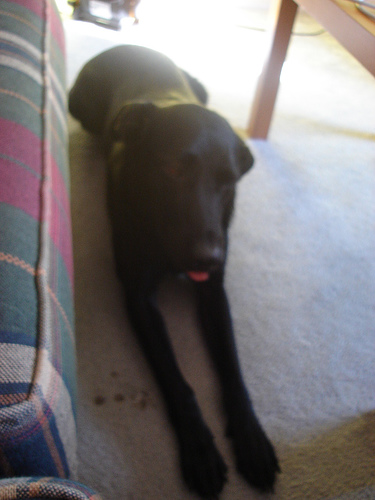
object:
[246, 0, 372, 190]
chair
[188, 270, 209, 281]
tongue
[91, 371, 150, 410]
stain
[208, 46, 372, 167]
carpet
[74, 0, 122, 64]
carpet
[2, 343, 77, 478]
stripe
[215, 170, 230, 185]
eye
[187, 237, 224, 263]
nose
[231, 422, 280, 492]
paw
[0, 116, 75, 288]
pink stripe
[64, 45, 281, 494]
dog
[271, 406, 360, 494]
trim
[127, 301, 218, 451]
black legs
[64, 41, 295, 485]
dogs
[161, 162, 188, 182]
left eye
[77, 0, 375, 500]
floor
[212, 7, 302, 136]
cord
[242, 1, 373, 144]
table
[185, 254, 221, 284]
mouth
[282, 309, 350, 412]
carpet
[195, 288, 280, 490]
legs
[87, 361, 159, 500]
carpet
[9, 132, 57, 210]
stripe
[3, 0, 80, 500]
chair